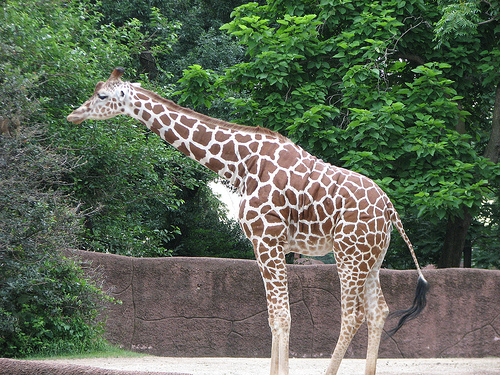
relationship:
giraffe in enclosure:
[66, 68, 439, 374] [5, 234, 497, 371]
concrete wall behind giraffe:
[63, 249, 500, 358] [66, 68, 439, 374]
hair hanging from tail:
[380, 275, 437, 345] [381, 194, 442, 357]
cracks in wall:
[114, 262, 328, 353] [58, 239, 498, 367]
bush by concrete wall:
[0, 67, 103, 360] [63, 249, 500, 358]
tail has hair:
[382, 213, 442, 352] [381, 282, 435, 343]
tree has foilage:
[5, 3, 190, 253] [7, 13, 97, 78]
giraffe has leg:
[66, 68, 439, 374] [252, 245, 296, 370]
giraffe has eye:
[66, 68, 439, 374] [93, 86, 110, 105]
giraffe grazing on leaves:
[66, 68, 439, 374] [38, 14, 89, 154]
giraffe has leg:
[66, 68, 439, 374] [318, 243, 365, 369]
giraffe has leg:
[66, 68, 439, 374] [358, 272, 398, 373]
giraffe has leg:
[66, 68, 439, 374] [276, 249, 290, 373]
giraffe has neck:
[66, 68, 439, 374] [119, 91, 257, 191]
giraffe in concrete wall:
[66, 68, 439, 374] [63, 249, 500, 358]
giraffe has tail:
[66, 68, 439, 374] [63, 67, 441, 373]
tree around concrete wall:
[175, 0, 500, 270] [63, 249, 500, 358]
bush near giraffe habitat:
[0, 67, 103, 360] [0, 246, 483, 370]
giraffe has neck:
[66, 68, 439, 374] [129, 93, 263, 192]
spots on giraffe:
[226, 145, 319, 218] [69, 55, 470, 373]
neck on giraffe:
[142, 85, 235, 178] [69, 55, 470, 373]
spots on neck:
[189, 114, 240, 165] [159, 100, 229, 193]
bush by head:
[0, 87, 79, 370] [52, 49, 146, 149]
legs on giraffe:
[251, 223, 418, 362] [230, 229, 412, 372]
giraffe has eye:
[66, 68, 439, 374] [97, 92, 107, 102]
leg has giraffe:
[257, 241, 297, 373] [66, 68, 439, 374]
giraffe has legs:
[66, 68, 439, 374] [319, 259, 397, 371]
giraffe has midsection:
[66, 68, 439, 374] [253, 155, 331, 240]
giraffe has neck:
[66, 68, 439, 374] [128, 83, 231, 168]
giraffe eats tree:
[66, 68, 439, 374] [33, 84, 63, 127]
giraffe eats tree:
[66, 68, 439, 374] [13, 17, 140, 227]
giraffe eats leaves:
[66, 68, 439, 374] [33, 77, 469, 318]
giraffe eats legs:
[66, 68, 439, 374] [255, 252, 393, 373]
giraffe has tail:
[66, 68, 439, 374] [386, 210, 435, 348]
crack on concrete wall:
[179, 281, 246, 344] [63, 249, 500, 358]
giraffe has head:
[66, 68, 439, 374] [61, 57, 148, 135]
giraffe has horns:
[66, 68, 439, 374] [101, 63, 130, 81]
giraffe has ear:
[66, 68, 439, 374] [126, 72, 147, 92]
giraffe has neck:
[66, 68, 439, 374] [128, 84, 224, 178]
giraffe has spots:
[66, 68, 439, 374] [266, 164, 295, 193]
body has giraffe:
[219, 126, 400, 266] [66, 68, 439, 374]